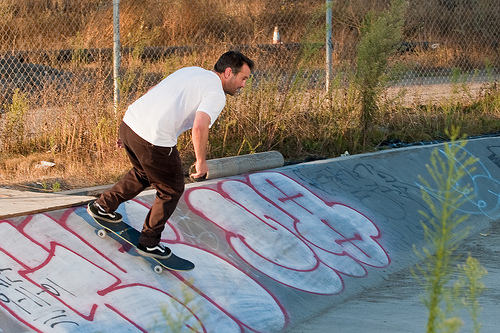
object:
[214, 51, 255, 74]
hair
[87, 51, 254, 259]
man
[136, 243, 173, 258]
shoe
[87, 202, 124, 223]
shoe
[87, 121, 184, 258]
pants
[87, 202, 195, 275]
board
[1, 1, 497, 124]
fence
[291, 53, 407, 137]
shrubs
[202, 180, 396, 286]
graffiti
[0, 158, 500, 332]
slope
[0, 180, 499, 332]
pavement